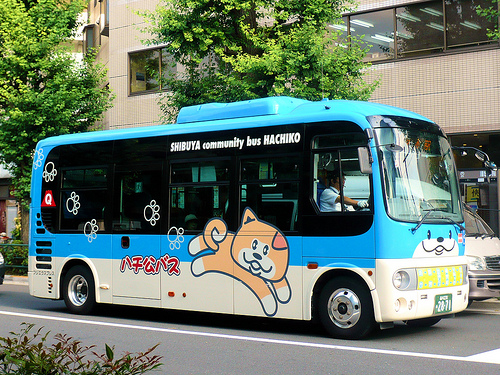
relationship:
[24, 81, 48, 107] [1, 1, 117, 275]
green leaf on plant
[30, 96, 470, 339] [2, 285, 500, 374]
bus driving on road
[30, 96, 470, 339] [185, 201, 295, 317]
bus with an animal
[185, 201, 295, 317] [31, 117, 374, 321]
animal on side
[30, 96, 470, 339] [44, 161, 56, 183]
bus with paw mark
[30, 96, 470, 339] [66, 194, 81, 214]
bus with paw mark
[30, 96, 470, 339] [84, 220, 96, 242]
bus with paw mark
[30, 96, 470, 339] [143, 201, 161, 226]
bus with paw mark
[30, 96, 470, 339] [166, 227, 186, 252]
bus with paw mark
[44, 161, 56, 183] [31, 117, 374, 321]
paw mark on side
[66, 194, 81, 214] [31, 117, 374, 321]
paw mark on side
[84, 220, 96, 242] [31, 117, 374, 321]
paw mark on side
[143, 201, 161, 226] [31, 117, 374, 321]
paw mark on side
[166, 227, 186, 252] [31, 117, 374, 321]
paw mark on side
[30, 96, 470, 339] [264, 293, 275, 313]
bus with paws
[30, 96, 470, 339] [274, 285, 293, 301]
bus with paws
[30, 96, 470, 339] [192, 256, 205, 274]
bus with paws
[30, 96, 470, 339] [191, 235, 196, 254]
bus with paws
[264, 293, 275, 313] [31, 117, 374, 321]
paws on side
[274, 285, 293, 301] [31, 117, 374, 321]
paws on side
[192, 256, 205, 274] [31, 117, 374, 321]
paws on side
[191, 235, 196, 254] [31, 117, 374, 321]
paws on side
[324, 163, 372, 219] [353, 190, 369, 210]
man with gloves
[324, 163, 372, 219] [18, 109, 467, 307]
man driving a bus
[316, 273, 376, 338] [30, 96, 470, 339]
front wheel of a bus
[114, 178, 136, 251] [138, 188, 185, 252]
small puddles behind tracks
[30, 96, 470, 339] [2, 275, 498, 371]
bus on road